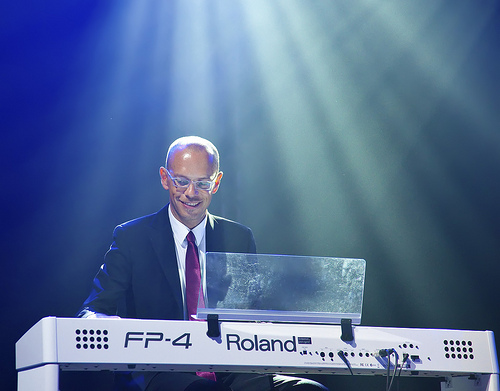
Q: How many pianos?
A: One.